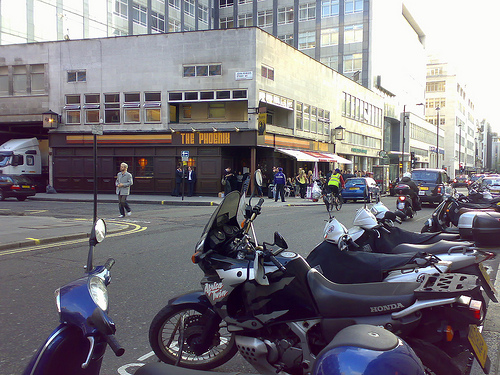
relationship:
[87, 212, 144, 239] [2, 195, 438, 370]
curb on road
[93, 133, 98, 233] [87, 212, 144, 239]
post on curb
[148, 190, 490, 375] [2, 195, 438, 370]
bike on road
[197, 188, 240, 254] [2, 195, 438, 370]
windshield on road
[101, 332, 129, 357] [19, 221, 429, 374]
handle on bike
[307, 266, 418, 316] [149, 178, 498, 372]
seat on bike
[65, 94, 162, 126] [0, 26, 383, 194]
windows on building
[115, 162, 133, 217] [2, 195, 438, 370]
man on road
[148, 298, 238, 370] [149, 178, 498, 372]
tire on bike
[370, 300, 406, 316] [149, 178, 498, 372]
brand on bike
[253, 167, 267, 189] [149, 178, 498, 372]
mirror on bike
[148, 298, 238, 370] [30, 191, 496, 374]
tire on bikes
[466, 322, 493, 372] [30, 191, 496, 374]
plate on bikes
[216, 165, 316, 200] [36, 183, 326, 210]
people on sidewalk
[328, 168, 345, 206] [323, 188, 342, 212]
people riding bicycle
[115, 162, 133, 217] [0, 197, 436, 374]
man crossing street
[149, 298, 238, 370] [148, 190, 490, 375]
tire on bike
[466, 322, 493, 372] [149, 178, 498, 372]
plate on bike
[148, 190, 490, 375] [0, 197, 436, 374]
bike on street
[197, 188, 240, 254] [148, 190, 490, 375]
windshield on bike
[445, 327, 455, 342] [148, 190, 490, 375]
light on bike